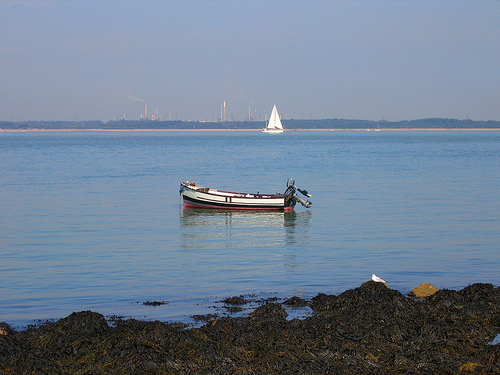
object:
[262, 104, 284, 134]
white sail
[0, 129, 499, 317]
water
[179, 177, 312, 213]
powerboat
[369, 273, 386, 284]
bird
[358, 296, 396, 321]
rock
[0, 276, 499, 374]
shoreline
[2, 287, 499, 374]
seaweed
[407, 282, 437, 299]
rock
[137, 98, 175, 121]
power plant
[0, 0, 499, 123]
sky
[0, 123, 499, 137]
shoreline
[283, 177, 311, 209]
engine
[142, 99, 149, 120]
smokestack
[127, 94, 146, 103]
smoke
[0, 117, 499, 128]
landscaping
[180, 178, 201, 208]
front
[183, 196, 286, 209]
stripe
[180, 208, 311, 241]
reflection